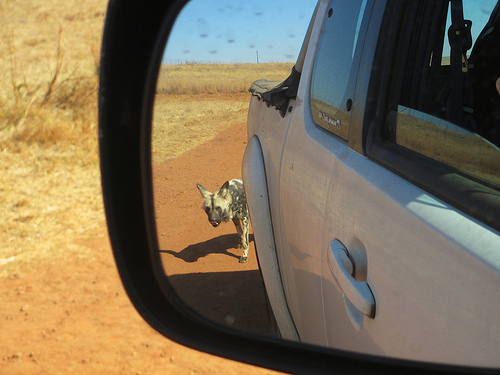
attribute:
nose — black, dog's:
[199, 215, 223, 232]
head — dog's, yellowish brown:
[181, 171, 230, 237]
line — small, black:
[205, 188, 228, 210]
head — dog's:
[183, 167, 241, 235]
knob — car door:
[315, 228, 381, 323]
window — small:
[274, 0, 372, 149]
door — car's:
[256, 0, 375, 345]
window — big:
[357, 0, 498, 232]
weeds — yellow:
[0, 39, 98, 199]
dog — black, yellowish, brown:
[192, 168, 260, 265]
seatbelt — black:
[442, 0, 481, 117]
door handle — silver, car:
[315, 228, 381, 327]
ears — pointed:
[187, 171, 237, 200]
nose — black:
[203, 218, 223, 228]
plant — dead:
[1, 50, 92, 163]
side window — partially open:
[386, 97, 498, 174]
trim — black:
[83, 0, 154, 321]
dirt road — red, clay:
[4, 197, 285, 373]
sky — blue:
[160, 0, 309, 74]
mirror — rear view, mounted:
[98, 6, 481, 373]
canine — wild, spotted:
[196, 179, 255, 262]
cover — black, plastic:
[246, 27, 302, 118]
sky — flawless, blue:
[162, 3, 310, 69]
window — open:
[380, 18, 483, 174]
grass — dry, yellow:
[0, 4, 109, 288]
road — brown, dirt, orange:
[9, 227, 213, 373]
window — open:
[386, 18, 483, 216]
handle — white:
[325, 238, 375, 318]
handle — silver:
[328, 238, 374, 316]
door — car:
[314, 11, 484, 359]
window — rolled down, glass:
[379, 101, 480, 171]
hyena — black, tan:
[198, 179, 256, 262]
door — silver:
[356, 213, 458, 325]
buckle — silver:
[452, 23, 470, 53]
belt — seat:
[436, 5, 485, 114]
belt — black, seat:
[446, 7, 466, 42]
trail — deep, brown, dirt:
[58, 270, 128, 357]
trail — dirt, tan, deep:
[54, 289, 97, 353]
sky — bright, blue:
[226, 11, 256, 43]